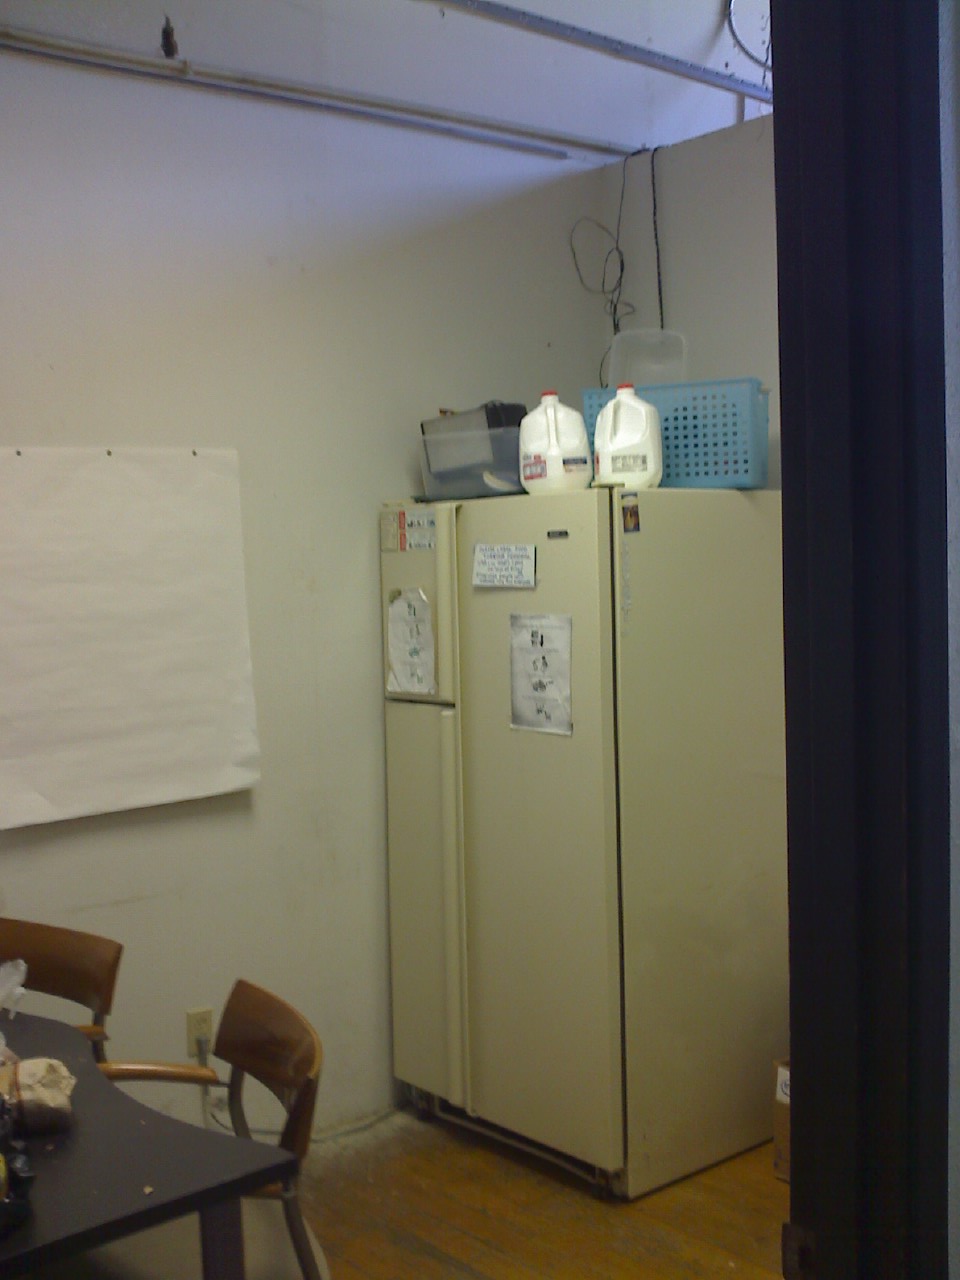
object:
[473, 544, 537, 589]
paper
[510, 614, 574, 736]
paper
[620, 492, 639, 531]
paper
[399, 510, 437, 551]
paper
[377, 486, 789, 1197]
fridge